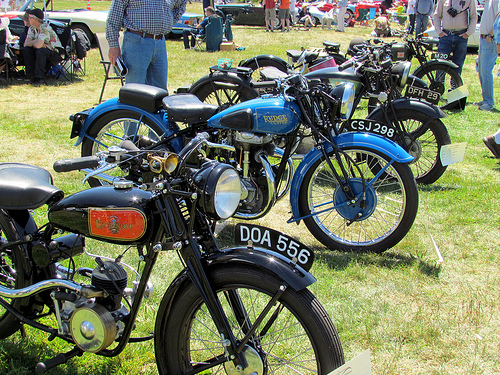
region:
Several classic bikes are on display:
[6, 5, 498, 371]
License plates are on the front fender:
[189, 33, 475, 262]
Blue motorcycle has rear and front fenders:
[75, 63, 423, 263]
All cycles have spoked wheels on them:
[6, 7, 498, 369]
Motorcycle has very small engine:
[47, 238, 168, 371]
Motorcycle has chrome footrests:
[191, 128, 303, 221]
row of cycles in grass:
[3, 35, 474, 373]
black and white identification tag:
[230, 220, 316, 275]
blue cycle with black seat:
[62, 70, 422, 260]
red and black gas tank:
[40, 176, 166, 250]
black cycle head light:
[188, 158, 245, 229]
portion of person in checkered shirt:
[98, 1, 182, 96]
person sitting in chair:
[15, 5, 67, 85]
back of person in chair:
[191, 4, 228, 54]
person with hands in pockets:
[430, 1, 480, 101]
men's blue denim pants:
[472, 30, 498, 112]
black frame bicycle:
[2, 82, 349, 374]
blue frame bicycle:
[71, 63, 419, 254]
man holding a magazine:
[105, 0, 190, 152]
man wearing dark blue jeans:
[430, 0, 478, 97]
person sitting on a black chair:
[17, 8, 72, 82]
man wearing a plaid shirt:
[104, 0, 174, 150]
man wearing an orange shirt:
[277, 0, 293, 32]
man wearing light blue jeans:
[472, 0, 498, 112]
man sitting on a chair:
[180, 2, 223, 50]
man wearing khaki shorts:
[261, 0, 278, 35]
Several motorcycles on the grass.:
[143, 54, 450, 235]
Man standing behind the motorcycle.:
[96, 10, 197, 118]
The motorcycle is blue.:
[201, 100, 402, 186]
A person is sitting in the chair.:
[16, 10, 93, 87]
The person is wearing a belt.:
[131, 29, 186, 49]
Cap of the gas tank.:
[103, 169, 149, 196]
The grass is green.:
[11, 83, 87, 161]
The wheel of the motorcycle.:
[301, 158, 413, 251]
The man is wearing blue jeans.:
[118, 30, 208, 116]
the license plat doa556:
[236, 218, 317, 265]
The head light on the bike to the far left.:
[189, 167, 264, 222]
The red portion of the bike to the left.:
[80, 202, 158, 256]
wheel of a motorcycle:
[156, 259, 338, 374]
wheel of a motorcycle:
[302, 146, 414, 254]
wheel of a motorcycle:
[375, 117, 447, 187]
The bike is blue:
[77, 74, 453, 283]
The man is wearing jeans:
[90, 3, 237, 157]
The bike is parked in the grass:
[57, 65, 447, 271]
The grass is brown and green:
[400, 180, 497, 326]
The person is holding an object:
[92, 30, 193, 115]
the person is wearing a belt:
[92, 28, 175, 98]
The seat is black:
[121, 38, 241, 147]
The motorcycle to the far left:
[4, 143, 384, 370]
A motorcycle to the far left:
[1, 148, 373, 370]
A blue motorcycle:
[72, 59, 427, 253]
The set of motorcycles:
[9, 22, 477, 372]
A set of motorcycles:
[1, 39, 480, 356]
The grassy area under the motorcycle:
[9, 27, 497, 364]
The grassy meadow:
[6, 26, 496, 368]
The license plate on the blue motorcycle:
[343, 119, 403, 139]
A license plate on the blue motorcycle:
[344, 115, 392, 143]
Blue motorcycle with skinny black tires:
[65, 73, 429, 256]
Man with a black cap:
[20, 9, 75, 87]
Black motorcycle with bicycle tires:
[2, 140, 347, 374]